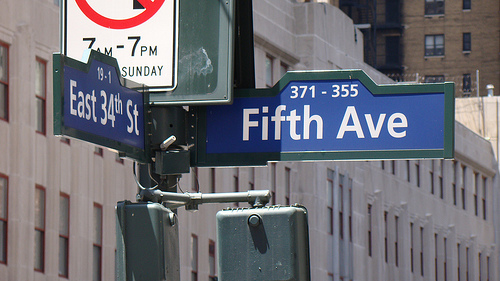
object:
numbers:
[104, 71, 116, 84]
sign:
[460, 70, 475, 97]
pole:
[135, 90, 185, 207]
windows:
[34, 182, 46, 275]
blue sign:
[191, 67, 457, 166]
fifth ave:
[243, 105, 408, 142]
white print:
[95, 65, 114, 83]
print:
[330, 83, 363, 100]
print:
[331, 105, 407, 139]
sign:
[54, 1, 184, 95]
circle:
[75, 0, 164, 29]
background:
[63, 1, 177, 88]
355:
[329, 82, 359, 98]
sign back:
[216, 205, 309, 279]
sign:
[53, 49, 150, 163]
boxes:
[155, 149, 191, 175]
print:
[238, 104, 325, 143]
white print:
[98, 89, 108, 126]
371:
[285, 83, 319, 98]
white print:
[68, 80, 99, 122]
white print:
[126, 99, 140, 136]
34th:
[97, 89, 123, 129]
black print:
[133, 0, 139, 7]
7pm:
[128, 35, 160, 57]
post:
[102, 36, 205, 268]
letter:
[241, 108, 260, 143]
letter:
[258, 106, 268, 140]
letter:
[270, 104, 285, 143]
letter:
[285, 109, 302, 142]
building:
[2, 1, 499, 279]